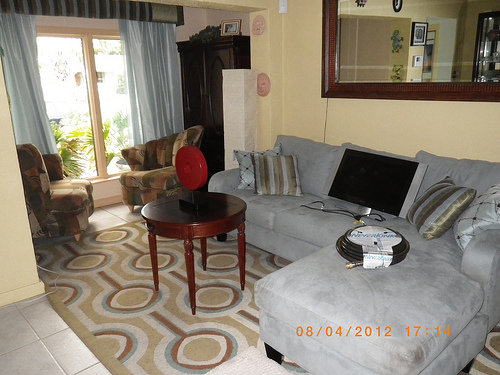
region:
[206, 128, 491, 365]
Gray sectional couch with pillows.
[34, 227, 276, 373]
Beige rug with white, blue and brown design.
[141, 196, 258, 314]
Antique round wooden table.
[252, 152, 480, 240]
Gold, silver and brown striped pillows.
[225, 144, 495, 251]
A splash of blue with brown trim on pillows.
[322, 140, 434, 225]
Silver and black flat screen television.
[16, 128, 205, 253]
Multi-color arm chairs.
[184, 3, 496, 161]
Light pastel yellow walls.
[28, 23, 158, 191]
Double windows with frame.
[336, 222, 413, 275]
Roll of brand new cable.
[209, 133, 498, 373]
grey fabric l-shaped couch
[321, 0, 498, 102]
mirror with cherrywood colored frame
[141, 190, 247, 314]
small cherrywood colored table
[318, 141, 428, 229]
small flatscreen tv sitting on a couch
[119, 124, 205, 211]
neutral colored fabric chair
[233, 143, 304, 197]
grey and brown couch pillows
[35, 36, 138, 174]
window with view of a sunny day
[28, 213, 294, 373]
large area rug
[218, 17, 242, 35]
small framed picture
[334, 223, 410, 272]
coiled coaxial cable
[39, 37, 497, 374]
a living room with furniture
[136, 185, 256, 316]
a small round table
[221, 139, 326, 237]
a gray couch in the living room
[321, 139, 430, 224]
a monitor sitting on the couch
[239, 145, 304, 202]
throw pillows on the couch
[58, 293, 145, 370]
a rug in the living room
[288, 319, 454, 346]
a print of the time and date the photo was taken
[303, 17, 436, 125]
a mirror on the wall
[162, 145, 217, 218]
a decorative piece on the table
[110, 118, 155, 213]
a chair in the living room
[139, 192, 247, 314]
a round dark brown table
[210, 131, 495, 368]
a light grey corner couch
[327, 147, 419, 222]
a flat screen TV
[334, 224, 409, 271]
a coiled black hose in packaging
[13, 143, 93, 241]
a plush brown chair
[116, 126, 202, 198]
a plush brown chair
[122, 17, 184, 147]
a blue curtain drape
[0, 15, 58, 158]
a blue curtain drape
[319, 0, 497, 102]
a large framed mirror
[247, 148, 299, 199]
a small pillow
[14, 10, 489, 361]
A living room in a home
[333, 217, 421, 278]
A brand new roll cable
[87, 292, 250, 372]
A rug that is tan blue brown and white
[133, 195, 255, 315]
A round table made of wood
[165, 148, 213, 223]
A red sculpture on a table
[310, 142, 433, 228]
A flat screen television on the couch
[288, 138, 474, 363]
A tan sectional couch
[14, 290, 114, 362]
The rug is on a tile floor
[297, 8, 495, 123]
A large mirror on the wall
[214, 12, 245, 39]
A framed picture atop a wooden cabinet